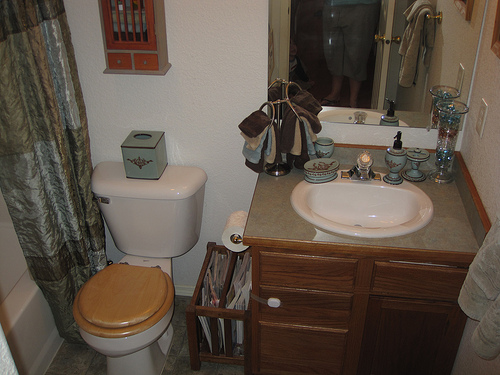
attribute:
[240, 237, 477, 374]
drawer — wooden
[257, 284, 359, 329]
drawer — wooden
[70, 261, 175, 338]
seat — brown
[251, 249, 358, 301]
drawer — brown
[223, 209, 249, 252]
toilet paper — white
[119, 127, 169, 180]
tissue — green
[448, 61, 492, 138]
outlet — white, electric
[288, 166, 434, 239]
sink — white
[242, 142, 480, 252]
top — granite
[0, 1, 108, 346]
curtain — grey, brown, dark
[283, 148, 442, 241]
sink — white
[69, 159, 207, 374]
toilet — white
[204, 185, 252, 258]
toilet paper — rolled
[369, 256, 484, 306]
drawer — wooden, brown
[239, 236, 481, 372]
cabinet — brown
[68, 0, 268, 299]
wall — white in colour